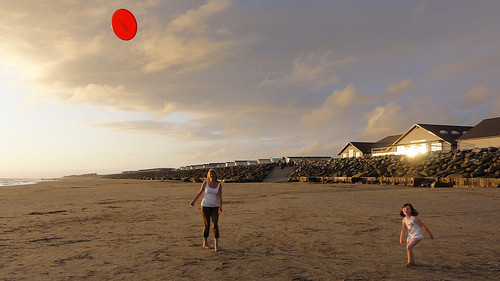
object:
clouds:
[456, 84, 487, 111]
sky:
[1, 0, 500, 176]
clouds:
[380, 78, 411, 101]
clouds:
[295, 84, 369, 128]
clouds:
[96, 120, 229, 142]